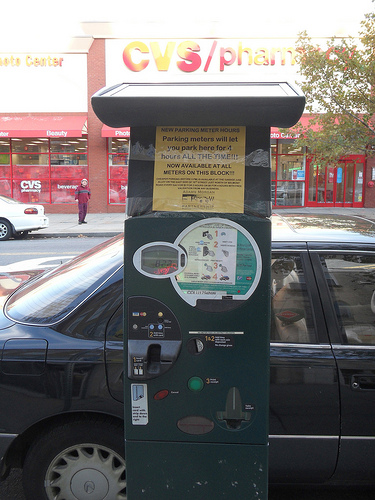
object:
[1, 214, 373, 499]
car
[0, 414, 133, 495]
wheel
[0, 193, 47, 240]
car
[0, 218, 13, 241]
wheel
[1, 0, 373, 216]
store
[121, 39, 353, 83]
sign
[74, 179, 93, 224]
man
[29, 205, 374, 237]
sidewalk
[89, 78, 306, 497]
parking meter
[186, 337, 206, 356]
coin slot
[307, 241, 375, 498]
door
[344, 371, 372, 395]
handle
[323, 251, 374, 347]
window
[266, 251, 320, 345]
window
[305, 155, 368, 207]
door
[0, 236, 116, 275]
street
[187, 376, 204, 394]
button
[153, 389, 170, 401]
button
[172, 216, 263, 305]
instructions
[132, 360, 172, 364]
money slot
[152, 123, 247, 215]
sign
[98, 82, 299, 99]
solar panel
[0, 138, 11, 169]
window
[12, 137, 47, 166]
window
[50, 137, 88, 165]
window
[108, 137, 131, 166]
window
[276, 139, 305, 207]
window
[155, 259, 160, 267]
number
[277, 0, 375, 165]
tree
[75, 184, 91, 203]
shirt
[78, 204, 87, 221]
pants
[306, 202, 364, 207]
frame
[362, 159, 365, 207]
frame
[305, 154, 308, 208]
frame